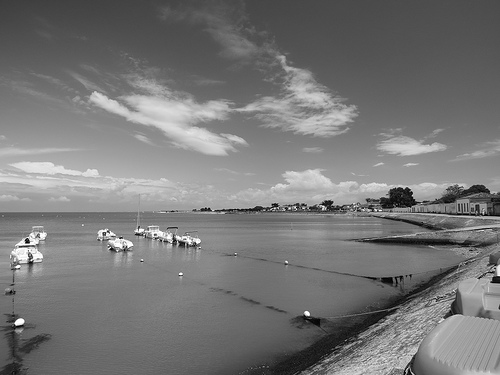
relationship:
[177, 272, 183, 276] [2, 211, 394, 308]
buoey on sea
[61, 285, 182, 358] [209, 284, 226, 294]
water has spot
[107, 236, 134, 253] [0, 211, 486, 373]
boat sitting in bay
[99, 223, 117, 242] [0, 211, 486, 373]
boat sitting in bay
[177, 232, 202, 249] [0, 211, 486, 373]
boat sitting in bay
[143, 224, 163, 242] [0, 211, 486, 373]
boat sitting in bay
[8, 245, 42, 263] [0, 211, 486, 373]
boat sitting in bay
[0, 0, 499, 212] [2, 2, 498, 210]
cloud in sky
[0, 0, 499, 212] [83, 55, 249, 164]
cloud in sky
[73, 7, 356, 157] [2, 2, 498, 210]
cloud in sky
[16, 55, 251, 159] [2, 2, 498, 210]
white clouds in sky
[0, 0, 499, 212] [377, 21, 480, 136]
cloud in sky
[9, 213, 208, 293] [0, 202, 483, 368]
boats on sea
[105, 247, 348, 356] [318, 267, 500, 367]
seas on port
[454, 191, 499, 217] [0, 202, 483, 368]
white house near sea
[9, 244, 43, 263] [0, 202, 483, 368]
boat on sea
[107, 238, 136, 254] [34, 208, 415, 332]
boat on water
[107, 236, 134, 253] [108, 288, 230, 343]
boat in water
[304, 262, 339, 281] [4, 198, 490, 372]
spot in water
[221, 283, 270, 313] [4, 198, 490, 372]
spot in water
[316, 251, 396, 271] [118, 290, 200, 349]
spot in water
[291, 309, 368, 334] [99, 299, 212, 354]
spot in water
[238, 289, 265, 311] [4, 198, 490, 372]
spot in water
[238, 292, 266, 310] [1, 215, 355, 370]
spot in water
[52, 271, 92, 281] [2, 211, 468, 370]
spot in water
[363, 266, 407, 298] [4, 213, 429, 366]
spot in water